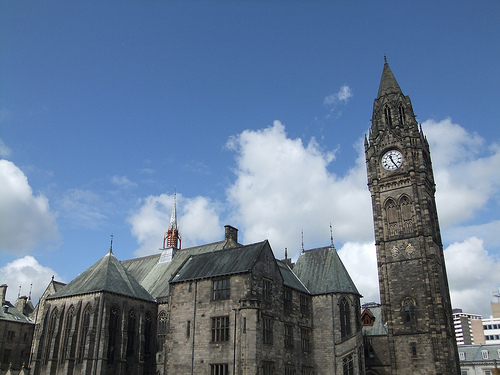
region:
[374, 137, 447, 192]
clock with roman numerals on it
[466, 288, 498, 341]
newer building on right side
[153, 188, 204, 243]
tall spire on top of building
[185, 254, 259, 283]
dark black roof of old building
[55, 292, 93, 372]
long narrow windows on old building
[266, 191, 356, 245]
white patch of clouds in sky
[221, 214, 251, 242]
brick chimeny on top of old building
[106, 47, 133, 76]
blue patch of sky in the air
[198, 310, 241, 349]
group of windows on old building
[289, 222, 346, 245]
two antenae on top of building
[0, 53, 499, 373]
The gray ancient building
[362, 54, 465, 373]
The gray pointed tower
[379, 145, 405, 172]
The white wall clock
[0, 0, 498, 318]
The blue cloudy sky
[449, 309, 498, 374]
The partially blocked white building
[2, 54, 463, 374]
The ancient sun beaten buildings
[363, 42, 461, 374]
The tall tower on the right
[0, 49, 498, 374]
An ancient town metropolis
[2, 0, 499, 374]
The bright ancient town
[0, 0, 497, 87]
The top blue sky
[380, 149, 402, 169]
A clock on the tower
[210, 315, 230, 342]
A window on the building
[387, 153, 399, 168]
The hands of the clock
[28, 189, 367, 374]
A building next to the clocktower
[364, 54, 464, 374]
A clocktower beneath the clouds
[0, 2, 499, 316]
The sky above the buildings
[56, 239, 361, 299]
The roof of the building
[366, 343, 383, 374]
A shadow on the building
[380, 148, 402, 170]
The clock is circular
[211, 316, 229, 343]
The window is rectangular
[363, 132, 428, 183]
the clock on a building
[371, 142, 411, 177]
w white clock on a building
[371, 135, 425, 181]
a big clock on a building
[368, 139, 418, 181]
the hand on a clock on a building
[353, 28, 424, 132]
the top on a building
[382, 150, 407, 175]
the hands on a clock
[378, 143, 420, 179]
numbers on a clock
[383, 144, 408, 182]
the big hand on a building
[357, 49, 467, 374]
a large clock tower on the end of the building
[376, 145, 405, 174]
a clock on the clock tower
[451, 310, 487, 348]
a parking garage in the distance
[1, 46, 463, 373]
a very old looking building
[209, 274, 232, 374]
rectangular windows on the side of the building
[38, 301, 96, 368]
arched windows on the side of the building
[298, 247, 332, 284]
stains on the roof of the building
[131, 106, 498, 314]
a few clouds in the sky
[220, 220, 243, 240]
a chimney near the middle of the roof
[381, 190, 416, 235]
decorative arches below the clock face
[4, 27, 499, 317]
The cloudy sky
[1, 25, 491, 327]
A cloudy sky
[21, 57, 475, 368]
The stone buildings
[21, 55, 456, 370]
A set of stone buildings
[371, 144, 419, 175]
The clock on the building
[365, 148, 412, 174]
The clock on the stone building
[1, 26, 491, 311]
A cloudy sky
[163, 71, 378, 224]
blue and white sky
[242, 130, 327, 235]
white clouds in sky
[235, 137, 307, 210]
white and puffy clouds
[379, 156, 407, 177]
clock is on tower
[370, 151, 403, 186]
clock has white face